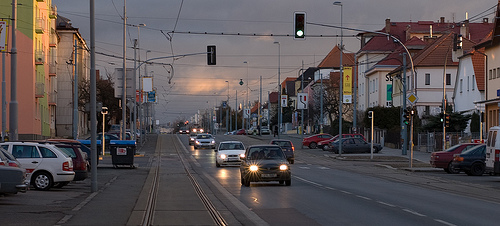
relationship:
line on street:
[356, 193, 369, 201] [173, 131, 497, 224]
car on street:
[213, 140, 246, 167] [139, 162, 206, 205]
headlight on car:
[220, 152, 227, 159] [213, 140, 244, 164]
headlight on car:
[238, 150, 247, 158] [213, 140, 244, 164]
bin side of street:
[103, 131, 143, 176] [0, 132, 499, 223]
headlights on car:
[247, 161, 288, 173] [233, 139, 298, 189]